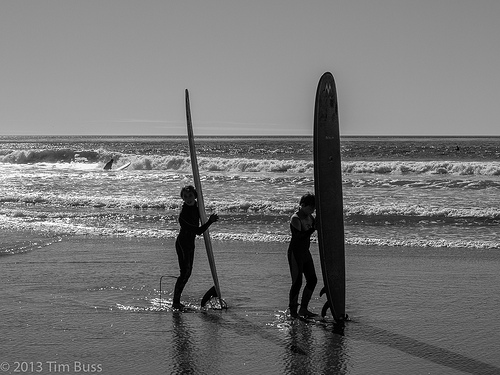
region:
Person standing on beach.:
[288, 205, 310, 344]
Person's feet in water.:
[257, 275, 344, 340]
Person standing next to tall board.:
[276, 207, 371, 297]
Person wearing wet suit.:
[281, 204, 345, 305]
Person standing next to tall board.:
[158, 175, 217, 338]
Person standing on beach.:
[147, 205, 216, 312]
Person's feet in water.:
[134, 237, 213, 364]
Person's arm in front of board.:
[167, 197, 258, 267]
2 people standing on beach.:
[116, 150, 356, 332]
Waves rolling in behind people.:
[33, 150, 411, 247]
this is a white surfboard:
[170, 82, 256, 327]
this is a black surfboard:
[279, 48, 384, 338]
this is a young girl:
[131, 171, 231, 321]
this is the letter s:
[95, 360, 107, 374]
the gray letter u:
[82, 359, 94, 372]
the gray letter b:
[73, 358, 84, 373]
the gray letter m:
[60, 362, 70, 374]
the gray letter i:
[52, 360, 59, 372]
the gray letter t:
[43, 356, 54, 373]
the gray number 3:
[32, 355, 43, 374]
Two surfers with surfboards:
[171, 70, 346, 318]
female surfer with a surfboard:
[170, 89, 229, 309]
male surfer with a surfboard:
[286, 72, 346, 321]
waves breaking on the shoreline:
[0, 145, 499, 250]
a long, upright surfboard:
[312, 70, 348, 321]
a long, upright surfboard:
[183, 86, 225, 306]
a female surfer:
[169, 185, 216, 311]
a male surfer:
[286, 193, 320, 318]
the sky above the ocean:
[0, 0, 499, 134]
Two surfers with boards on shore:
[166, 71, 347, 321]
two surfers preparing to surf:
[148, 42, 383, 327]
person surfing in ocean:
[72, 145, 132, 185]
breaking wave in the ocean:
[13, 136, 116, 169]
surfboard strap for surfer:
[143, 262, 188, 307]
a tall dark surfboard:
[296, 55, 352, 331]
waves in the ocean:
[390, 138, 481, 219]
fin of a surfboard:
[195, 265, 228, 316]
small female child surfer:
[278, 67, 364, 332]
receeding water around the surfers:
[135, 275, 317, 343]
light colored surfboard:
[168, 82, 236, 322]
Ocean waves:
[371, 148, 468, 245]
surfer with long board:
[276, 68, 376, 339]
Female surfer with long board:
[144, 87, 231, 368]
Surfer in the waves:
[91, 135, 138, 191]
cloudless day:
[34, 18, 402, 81]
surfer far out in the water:
[400, 136, 491, 191]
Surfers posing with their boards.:
[113, 171, 374, 321]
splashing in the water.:
[141, 282, 363, 357]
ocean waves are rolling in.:
[354, 152, 488, 212]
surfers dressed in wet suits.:
[156, 176, 384, 331]